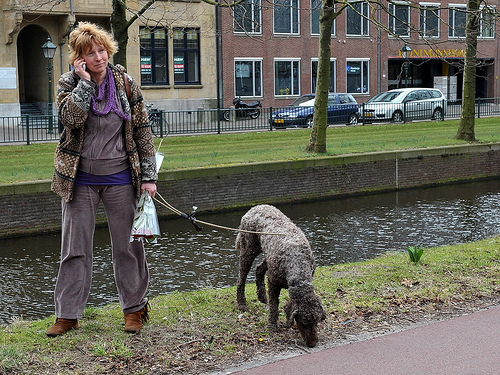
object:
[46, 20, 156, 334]
woman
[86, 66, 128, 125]
scarf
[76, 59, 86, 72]
cell phone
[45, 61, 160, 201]
jogging suit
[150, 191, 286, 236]
leash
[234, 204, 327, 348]
dog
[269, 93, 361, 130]
car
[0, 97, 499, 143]
street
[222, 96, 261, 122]
motorcycle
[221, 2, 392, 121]
wall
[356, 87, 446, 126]
van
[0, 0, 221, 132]
building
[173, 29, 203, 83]
window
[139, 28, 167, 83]
window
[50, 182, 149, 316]
pants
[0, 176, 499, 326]
canal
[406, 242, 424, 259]
plant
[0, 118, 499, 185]
grass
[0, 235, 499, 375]
spot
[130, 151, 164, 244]
paper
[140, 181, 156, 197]
hand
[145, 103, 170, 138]
bike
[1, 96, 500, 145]
fence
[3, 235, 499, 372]
ground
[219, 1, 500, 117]
building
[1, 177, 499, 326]
water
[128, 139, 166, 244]
flowers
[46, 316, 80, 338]
boot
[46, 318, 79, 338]
right foot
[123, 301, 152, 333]
boot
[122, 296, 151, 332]
left foot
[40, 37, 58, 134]
lightpost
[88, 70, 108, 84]
neck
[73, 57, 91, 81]
left hand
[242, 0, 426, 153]
tree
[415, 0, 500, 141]
tree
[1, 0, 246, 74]
tree